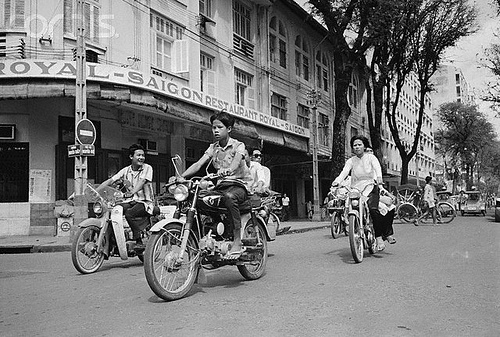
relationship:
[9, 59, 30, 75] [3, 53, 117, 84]
letter on sign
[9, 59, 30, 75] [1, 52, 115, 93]
letter on sign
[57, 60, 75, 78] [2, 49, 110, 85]
letter on sign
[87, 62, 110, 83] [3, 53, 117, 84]
letter on sign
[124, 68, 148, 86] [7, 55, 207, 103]
letter on sign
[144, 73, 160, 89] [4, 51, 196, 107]
letter on sign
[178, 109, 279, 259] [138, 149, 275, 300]
boy on motorcycle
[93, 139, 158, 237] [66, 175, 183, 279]
boy riding motorcycle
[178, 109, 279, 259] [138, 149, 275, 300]
boy riding motorcycle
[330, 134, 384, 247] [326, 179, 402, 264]
woman on motorcycle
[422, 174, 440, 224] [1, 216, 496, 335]
person walking in street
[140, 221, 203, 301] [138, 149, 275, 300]
wheel on motorcycle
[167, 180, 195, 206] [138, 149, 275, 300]
head light on motorcycle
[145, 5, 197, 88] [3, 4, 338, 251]
window on building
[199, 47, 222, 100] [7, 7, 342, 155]
window on building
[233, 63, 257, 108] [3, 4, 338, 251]
window on building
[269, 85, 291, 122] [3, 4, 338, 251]
window on building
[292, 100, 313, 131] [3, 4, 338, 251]
window on building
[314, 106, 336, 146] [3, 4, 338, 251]
window on building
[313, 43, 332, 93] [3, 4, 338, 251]
window on building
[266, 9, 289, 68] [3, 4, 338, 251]
window on building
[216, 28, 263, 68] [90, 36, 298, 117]
window on building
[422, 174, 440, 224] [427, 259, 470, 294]
person walking across road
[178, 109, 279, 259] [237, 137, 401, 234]
boy leading bikes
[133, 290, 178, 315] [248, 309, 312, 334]
shadow on road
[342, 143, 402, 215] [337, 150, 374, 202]
person wearing shirt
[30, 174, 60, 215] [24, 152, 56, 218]
writing on poster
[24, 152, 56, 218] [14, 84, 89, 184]
poster on building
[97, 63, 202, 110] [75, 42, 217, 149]
saigon on building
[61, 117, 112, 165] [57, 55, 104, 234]
sign on pole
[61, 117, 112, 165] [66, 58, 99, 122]
sign on pole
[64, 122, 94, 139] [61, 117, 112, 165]
stripe on sign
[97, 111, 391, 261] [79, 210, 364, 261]
people on bikes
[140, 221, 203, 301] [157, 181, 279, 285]
wheel on bike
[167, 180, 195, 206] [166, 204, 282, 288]
head light on bike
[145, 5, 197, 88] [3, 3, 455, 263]
window on a building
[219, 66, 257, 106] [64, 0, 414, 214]
window on a building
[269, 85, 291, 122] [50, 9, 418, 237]
window on a building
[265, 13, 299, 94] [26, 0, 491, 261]
window on a building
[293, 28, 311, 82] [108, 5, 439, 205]
window on a building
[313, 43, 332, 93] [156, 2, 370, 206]
window on a building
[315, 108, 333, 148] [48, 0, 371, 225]
window on a building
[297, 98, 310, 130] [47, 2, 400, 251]
window on a building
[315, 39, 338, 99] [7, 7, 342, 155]
window on building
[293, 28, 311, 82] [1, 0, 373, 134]
window on building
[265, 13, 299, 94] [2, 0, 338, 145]
window on building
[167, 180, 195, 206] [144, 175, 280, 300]
head light on bike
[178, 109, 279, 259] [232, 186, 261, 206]
boy sitting on bike seat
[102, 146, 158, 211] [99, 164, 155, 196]
man wearing shirt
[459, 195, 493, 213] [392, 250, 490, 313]
car on street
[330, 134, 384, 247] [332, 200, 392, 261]
woman on bike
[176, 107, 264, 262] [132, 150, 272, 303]
person on bike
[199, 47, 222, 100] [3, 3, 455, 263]
window on building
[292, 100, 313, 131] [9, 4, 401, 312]
window on building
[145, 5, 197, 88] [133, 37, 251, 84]
window on a buildind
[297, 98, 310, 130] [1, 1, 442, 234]
window on a building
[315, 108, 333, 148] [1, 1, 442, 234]
window on building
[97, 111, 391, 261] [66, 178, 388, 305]
people riding bikes